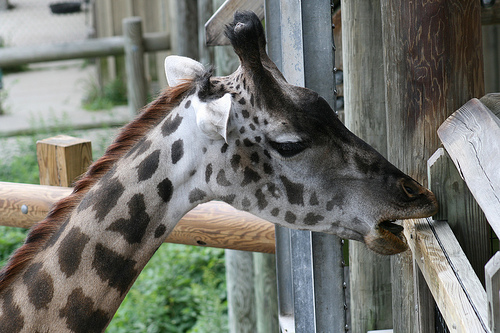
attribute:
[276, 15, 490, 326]
fence — wooden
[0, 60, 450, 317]
giraffe — baby